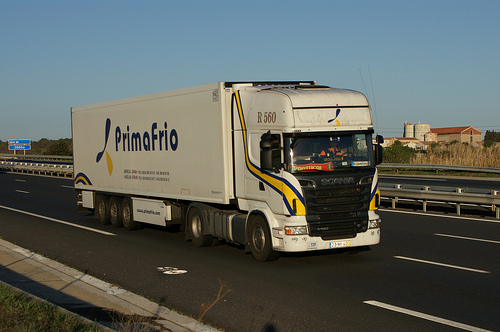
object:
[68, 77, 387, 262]
truck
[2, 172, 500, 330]
road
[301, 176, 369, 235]
grill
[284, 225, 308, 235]
lights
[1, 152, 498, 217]
fence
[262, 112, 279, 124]
number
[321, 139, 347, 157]
person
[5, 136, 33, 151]
sign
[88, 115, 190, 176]
logo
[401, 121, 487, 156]
building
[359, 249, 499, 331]
lines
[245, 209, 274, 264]
wheels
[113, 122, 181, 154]
writing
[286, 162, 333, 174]
tag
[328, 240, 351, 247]
plate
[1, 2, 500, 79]
sky